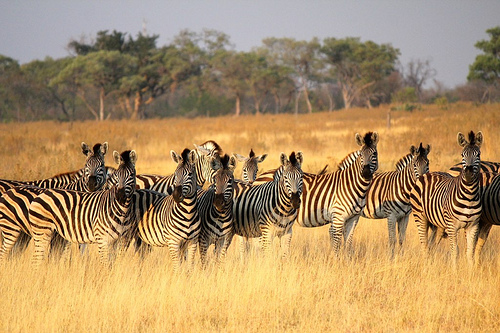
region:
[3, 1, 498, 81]
blue of daytime sky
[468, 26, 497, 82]
green leaves on tree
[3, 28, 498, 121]
green trees on horizon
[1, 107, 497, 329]
field of dried grass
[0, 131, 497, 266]
herd of standing zebras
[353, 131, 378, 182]
head with black mane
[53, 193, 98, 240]
stripes on zebra torso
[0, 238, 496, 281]
feet obstructed by tall grass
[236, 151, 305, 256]
zebra looking at camera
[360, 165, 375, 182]
black nose of zebra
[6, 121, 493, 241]
these are the zebras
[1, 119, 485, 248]
they are many in number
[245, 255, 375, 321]
these are the grass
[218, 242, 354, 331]
the grass are dry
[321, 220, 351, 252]
these are the legs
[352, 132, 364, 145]
this is the ear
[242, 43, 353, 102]
they are at the back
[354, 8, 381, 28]
this is the sky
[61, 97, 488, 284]
the zebras area arnged n a row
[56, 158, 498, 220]
zebras are looking in the same directuion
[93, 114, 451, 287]
they have white and black strpes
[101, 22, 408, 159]
trees are seen at the ackground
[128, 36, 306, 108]
trees are green in color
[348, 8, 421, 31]
the sky is clear blue in color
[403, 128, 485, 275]
zebra standing in field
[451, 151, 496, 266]
zebra standing in field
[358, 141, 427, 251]
zebra standing in field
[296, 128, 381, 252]
zebra standing in field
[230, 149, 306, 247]
zebra standing in field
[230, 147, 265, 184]
zebra standing in field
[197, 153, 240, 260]
zebra standing in field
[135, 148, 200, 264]
zebra standing in field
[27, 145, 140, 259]
zebra standing in field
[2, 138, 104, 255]
zebra standing in field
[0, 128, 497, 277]
a herd of zebras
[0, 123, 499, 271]
black and white animals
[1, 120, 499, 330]
tall grass on the ground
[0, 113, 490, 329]
the grass is yellow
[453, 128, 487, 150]
two large ears sticking off the top of the head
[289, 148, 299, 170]
black hair between the ears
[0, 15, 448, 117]
a row of trees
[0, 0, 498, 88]
no clouds visible in the sky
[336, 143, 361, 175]
tall hair on the back